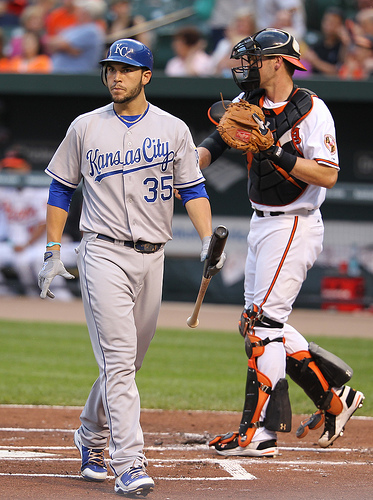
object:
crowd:
[2, 1, 373, 77]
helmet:
[100, 38, 154, 83]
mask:
[228, 36, 262, 93]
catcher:
[161, 26, 368, 462]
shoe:
[214, 430, 280, 458]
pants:
[241, 210, 329, 439]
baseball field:
[2, 292, 369, 499]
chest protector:
[229, 80, 324, 210]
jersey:
[43, 99, 206, 243]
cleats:
[114, 464, 157, 496]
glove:
[33, 252, 75, 298]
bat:
[185, 222, 229, 329]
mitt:
[206, 95, 273, 155]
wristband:
[43, 239, 64, 251]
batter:
[37, 32, 235, 498]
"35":
[140, 174, 174, 205]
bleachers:
[0, 0, 372, 94]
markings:
[162, 427, 254, 489]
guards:
[206, 303, 296, 448]